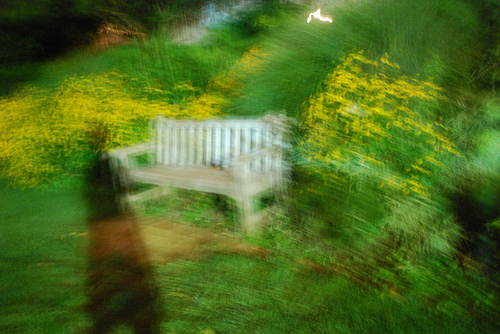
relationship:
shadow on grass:
[71, 119, 182, 332] [0, 0, 499, 334]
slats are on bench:
[161, 133, 244, 165] [93, 101, 308, 240]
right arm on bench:
[227, 141, 279, 186] [93, 101, 308, 240]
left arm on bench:
[105, 125, 155, 173] [93, 101, 308, 240]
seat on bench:
[141, 158, 247, 195] [93, 101, 308, 240]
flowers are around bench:
[7, 52, 441, 191] [93, 101, 308, 240]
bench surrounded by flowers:
[93, 101, 308, 240] [7, 52, 441, 191]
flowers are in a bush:
[310, 46, 439, 201] [286, 34, 469, 270]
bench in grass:
[93, 101, 308, 240] [0, 0, 499, 334]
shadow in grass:
[71, 119, 182, 332] [0, 0, 499, 334]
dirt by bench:
[90, 211, 256, 265] [93, 101, 308, 240]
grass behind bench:
[111, 33, 265, 108] [93, 101, 308, 240]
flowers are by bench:
[7, 52, 441, 191] [93, 101, 308, 240]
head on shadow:
[83, 121, 117, 149] [71, 119, 182, 332]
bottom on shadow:
[79, 157, 175, 329] [71, 119, 182, 332]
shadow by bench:
[71, 119, 182, 332] [93, 101, 308, 240]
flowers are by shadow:
[7, 52, 441, 191] [71, 119, 182, 332]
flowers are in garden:
[7, 52, 441, 191] [0, 2, 499, 333]